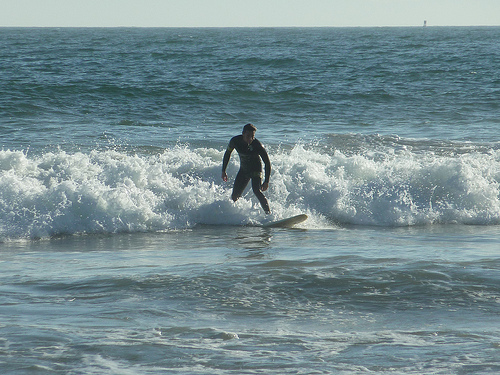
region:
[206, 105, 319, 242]
The man is surfing.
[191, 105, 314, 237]
The man is on a surfboard.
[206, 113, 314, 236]
The man is wearing a wetsuit.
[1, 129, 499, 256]
The wave is white.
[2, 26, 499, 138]
The water is blue.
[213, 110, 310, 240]
The man has hair.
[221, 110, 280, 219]
The man's hair is short.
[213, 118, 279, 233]
Man's arms are down by his side.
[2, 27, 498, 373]
The water is aggressive.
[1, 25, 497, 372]
The water is splashing.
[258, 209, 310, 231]
THE MAN IS SURFING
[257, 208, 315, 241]
THIS IS A SURFBOARD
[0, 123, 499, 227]
THE MAN IS ON A WAVE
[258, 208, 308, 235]
THE MAN IS ON A SURFBOARD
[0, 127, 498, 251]
THE WAVE IS BREAKING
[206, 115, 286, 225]
THE MAN IS WET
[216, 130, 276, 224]
THE MAN IS WEARING A WET SUIT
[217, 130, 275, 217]
THE WET SUIT IS BLACK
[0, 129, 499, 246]
THE CREST OF THE WAVE IS WHITE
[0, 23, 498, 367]
THE OCEAN IS VAST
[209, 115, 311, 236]
The wetsuit has sleeves.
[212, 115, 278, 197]
The sleeves are long.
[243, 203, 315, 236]
The surfboard is white.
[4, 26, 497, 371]
The water is wavy.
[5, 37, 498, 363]
The water is choppy.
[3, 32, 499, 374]
The water is zealous.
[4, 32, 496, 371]
The water is boisterous.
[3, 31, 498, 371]
The water is rambunctious.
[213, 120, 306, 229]
man on surfboard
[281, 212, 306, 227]
tip of white surfboard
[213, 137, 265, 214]
black full wet suit on man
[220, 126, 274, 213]
man standing in crouched position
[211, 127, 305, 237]
surfer on a wave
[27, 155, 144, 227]
white water from wave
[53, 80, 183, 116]
small wave forming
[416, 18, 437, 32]
small ship in background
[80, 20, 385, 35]
horizon line from ocean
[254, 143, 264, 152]
small logo on side of suit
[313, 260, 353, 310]
part of a water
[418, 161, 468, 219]
part of a splash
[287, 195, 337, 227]
edge of a voard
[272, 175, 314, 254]
part of a board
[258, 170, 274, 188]
part of a hand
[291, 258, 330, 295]
part of a water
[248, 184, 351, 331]
part of a board